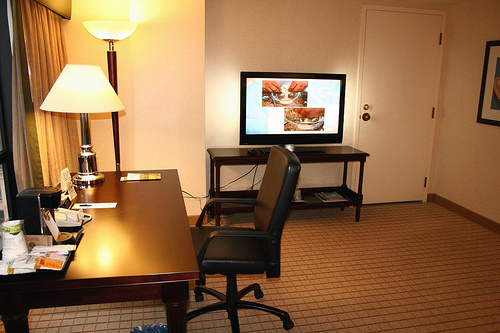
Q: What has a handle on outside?
A: The door.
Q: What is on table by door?
A: A television.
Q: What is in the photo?
A: Door.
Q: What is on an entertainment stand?
A: A television.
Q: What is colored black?
A: A chair.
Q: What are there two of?
A: Lamps.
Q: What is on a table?
A: A television.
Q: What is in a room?
A: A door.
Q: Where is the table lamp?
A: Desk.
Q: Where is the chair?
A: By desk.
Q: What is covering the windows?
A: Curtains.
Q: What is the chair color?
A: Black.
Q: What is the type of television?
A: Flatscreen.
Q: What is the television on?
A: Table.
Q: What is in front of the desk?
A: A chair.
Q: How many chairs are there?
A: 1.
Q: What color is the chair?
A: Black.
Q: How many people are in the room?
A: Zero.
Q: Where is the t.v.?
A: On the t.v. stand.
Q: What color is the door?
A: White.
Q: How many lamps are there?
A: 2.